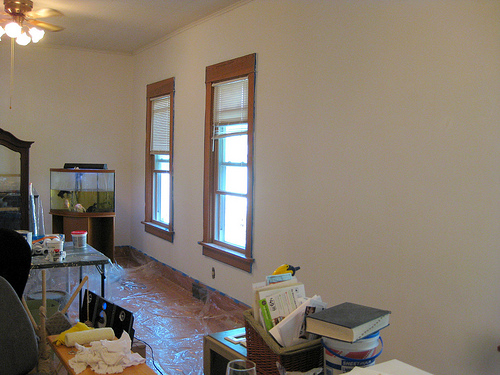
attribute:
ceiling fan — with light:
[0, 1, 63, 52]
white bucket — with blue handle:
[318, 330, 385, 369]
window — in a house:
[138, 72, 178, 244]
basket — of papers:
[240, 307, 329, 372]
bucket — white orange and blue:
[317, 333, 386, 371]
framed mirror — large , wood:
[0, 121, 40, 231]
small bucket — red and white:
[68, 226, 88, 252]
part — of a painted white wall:
[326, 91, 444, 228]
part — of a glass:
[226, 356, 260, 373]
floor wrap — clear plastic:
[116, 260, 201, 343]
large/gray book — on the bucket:
[306, 299, 393, 346]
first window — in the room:
[199, 51, 257, 272]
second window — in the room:
[141, 75, 178, 243]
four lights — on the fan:
[1, 16, 46, 49]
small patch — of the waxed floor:
[175, 317, 200, 372]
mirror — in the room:
[1, 141, 21, 231]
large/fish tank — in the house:
[46, 158, 117, 217]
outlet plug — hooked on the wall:
[208, 264, 217, 280]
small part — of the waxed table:
[72, 247, 82, 258]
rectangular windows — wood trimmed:
[141, 51, 258, 277]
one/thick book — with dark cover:
[302, 300, 392, 340]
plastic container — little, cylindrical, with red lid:
[68, 227, 90, 253]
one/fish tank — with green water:
[46, 156, 119, 216]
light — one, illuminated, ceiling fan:
[1, 19, 49, 57]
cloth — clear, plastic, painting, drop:
[26, 233, 251, 373]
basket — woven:
[241, 305, 324, 373]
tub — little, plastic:
[317, 331, 384, 371]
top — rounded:
[221, 357, 261, 372]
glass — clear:
[216, 352, 260, 372]